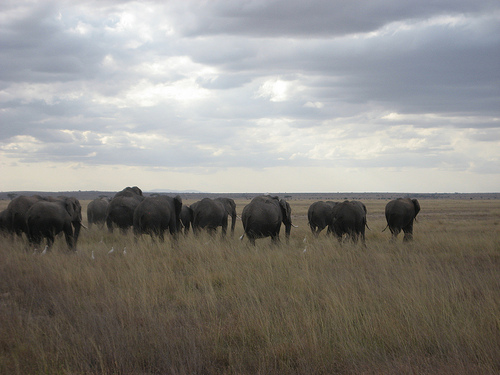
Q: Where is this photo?
A: Africa.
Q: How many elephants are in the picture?
A: Ten.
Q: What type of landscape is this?
A: Savannah.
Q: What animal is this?
A: Elephant.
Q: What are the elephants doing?
A: Walking.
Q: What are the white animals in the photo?
A: Birds.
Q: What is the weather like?
A: Overcast.